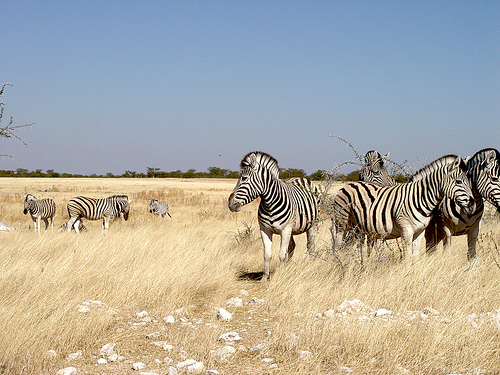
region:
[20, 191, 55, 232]
First zebra to the left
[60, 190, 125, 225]
Second zebra to the left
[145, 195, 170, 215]
Third zebra to the left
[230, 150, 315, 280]
Zebra in the middle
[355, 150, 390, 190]
Zebra in the back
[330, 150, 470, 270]
Zebra second from the right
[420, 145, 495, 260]
First zebra to the right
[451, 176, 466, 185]
Second zebra's right eye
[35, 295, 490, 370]
White stones laying on the ground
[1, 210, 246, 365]
Grass that the zebras are grazing on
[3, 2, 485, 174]
the sky is blue.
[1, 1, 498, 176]
the sky is clear.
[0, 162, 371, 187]
trees growing in the distance.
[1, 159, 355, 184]
the trees are green.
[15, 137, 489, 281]
zebras in a field.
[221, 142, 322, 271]
zebra is black and white.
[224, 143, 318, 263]
the zebra is striped.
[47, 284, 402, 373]
rocks on the ground.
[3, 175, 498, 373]
the grass is dry.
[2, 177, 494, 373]
the grass is tan.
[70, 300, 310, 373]
rocks in large pasture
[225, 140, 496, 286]
group of four zebras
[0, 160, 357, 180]
trees in far background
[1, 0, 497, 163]
large clear blue sky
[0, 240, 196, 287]
brown dead pasture grass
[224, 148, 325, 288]
unique large creature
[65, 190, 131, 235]
animal with black and white stripes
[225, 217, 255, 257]
dead brush in pasture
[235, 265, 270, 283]
black shadow of large animal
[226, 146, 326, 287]
large mammal with four legs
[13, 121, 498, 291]
group of seven zebras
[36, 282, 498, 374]
white rocks among the grass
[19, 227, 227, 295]
brown tall grass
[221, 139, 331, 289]
black and white zebra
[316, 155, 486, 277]
zebra with black and white stripes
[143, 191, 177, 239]
zebra standing in the grass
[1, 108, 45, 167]
some tree branches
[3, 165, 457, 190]
tree line behind beyond the grass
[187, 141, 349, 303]
zebra looking at something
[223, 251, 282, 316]
the zebra's shadow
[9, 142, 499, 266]
seven zebras on a grassy field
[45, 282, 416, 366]
rocky patches amid light brown grass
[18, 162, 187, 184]
dark trees on grassy horizon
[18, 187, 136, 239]
two zebras facing in different directions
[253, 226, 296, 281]
two zebra legs in a grassy field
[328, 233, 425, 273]
zebra legs partially hidden by tall grass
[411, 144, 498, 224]
two zebra heads facing the same direction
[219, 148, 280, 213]
black and white zebra head in profile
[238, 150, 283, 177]
black and white zebra mane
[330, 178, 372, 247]
black and white zebra rear